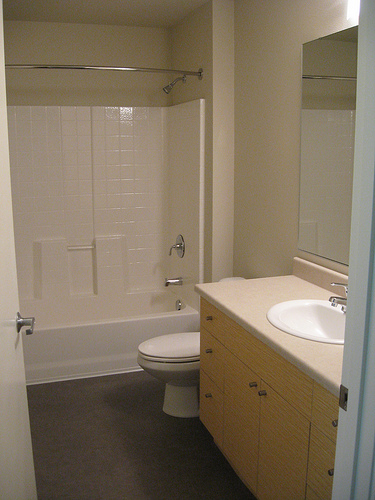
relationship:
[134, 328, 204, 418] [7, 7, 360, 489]
toilet in bathroom